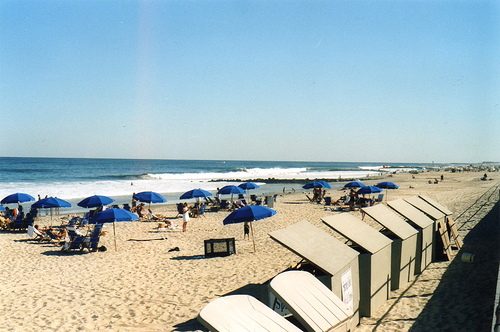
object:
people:
[200, 202, 208, 219]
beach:
[5, 162, 499, 330]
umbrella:
[87, 205, 144, 251]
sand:
[107, 261, 179, 296]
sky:
[3, 1, 497, 161]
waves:
[74, 183, 136, 193]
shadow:
[365, 177, 499, 328]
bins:
[264, 219, 364, 318]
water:
[1, 159, 134, 187]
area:
[214, 176, 315, 187]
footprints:
[212, 280, 224, 292]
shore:
[34, 182, 376, 214]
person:
[49, 225, 61, 245]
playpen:
[202, 236, 237, 257]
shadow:
[168, 251, 214, 266]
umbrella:
[216, 202, 280, 253]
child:
[173, 200, 191, 232]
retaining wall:
[330, 161, 394, 184]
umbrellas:
[179, 186, 217, 210]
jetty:
[209, 174, 311, 187]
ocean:
[1, 155, 433, 200]